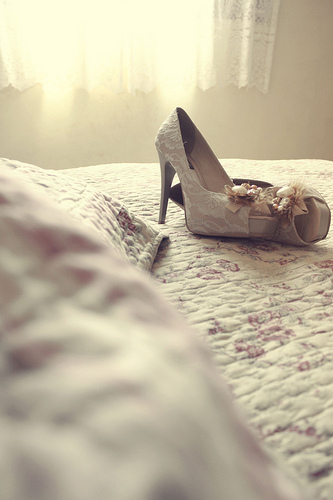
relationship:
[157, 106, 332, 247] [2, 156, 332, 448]
high heels are on a bed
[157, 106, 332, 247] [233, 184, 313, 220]
high heels have a decoration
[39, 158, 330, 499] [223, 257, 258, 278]
sheet has a design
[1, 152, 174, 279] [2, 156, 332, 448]
pillow on a bed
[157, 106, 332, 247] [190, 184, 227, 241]
high heels have a lace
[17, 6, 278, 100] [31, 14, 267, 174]
curtain has sunlight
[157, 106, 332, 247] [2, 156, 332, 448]
high heels on a bed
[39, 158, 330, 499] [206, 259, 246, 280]
sheet has a print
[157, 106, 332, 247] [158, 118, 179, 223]
high heels has a back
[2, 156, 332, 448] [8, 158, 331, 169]
bed has an edge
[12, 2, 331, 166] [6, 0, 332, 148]
wall in background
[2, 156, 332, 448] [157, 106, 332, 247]
bed has a high heels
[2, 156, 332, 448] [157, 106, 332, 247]
bed holding high heels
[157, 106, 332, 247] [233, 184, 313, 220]
high heels has a decoration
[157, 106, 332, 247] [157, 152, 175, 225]
high heels has a four inch heel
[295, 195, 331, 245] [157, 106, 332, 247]
open toed are high heels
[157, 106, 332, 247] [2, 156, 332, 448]
high heels are laying on a bed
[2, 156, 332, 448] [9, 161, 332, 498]
bed has a blanket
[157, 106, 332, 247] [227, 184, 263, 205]
high heels has a flower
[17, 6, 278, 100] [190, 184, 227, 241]
curtain have a lace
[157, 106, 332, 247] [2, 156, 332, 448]
high heels are sitting on a bed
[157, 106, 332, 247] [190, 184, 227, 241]
high heels have lace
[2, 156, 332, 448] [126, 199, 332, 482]
bed has a pattern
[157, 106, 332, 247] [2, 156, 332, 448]
high heels are resting on a bed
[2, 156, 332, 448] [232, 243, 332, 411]
bed has a pattern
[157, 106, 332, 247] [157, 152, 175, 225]
high heels have a four inch heel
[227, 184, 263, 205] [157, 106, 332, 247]
flower on a high heels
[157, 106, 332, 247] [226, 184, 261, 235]
high heels have a lace pattern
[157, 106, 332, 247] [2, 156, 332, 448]
high heels on bed